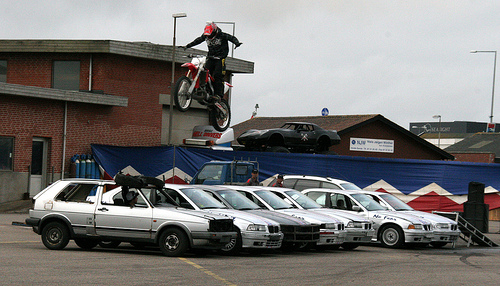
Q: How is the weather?
A: It is cloudy.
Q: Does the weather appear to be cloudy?
A: Yes, it is cloudy.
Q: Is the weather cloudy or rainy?
A: It is cloudy.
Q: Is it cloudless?
A: No, it is cloudy.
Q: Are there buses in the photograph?
A: No, there are no buses.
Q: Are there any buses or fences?
A: No, there are no buses or fences.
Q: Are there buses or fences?
A: No, there are no fences or buses.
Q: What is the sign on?
A: The sign is on the building.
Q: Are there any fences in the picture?
A: No, there are no fences.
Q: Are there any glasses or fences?
A: No, there are no fences or glasses.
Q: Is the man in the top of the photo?
A: Yes, the man is in the top of the image.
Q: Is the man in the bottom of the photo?
A: No, the man is in the top of the image.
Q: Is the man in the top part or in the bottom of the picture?
A: The man is in the top of the image.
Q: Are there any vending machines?
A: No, there are no vending machines.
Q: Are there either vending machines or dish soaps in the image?
A: No, there are no vending machines or dish soaps.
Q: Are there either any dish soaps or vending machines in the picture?
A: No, there are no vending machines or dish soaps.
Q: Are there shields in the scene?
A: No, there are no shields.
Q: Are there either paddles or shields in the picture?
A: No, there are no shields or paddles.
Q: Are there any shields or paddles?
A: No, there are no shields or paddles.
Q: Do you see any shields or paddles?
A: No, there are no shields or paddles.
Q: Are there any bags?
A: No, there are no bags.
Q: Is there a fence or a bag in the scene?
A: No, there are no bags or fences.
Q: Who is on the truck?
A: The people are on the truck.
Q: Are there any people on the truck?
A: Yes, there are people on the truck.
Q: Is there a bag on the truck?
A: No, there are people on the truck.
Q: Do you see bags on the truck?
A: No, there are people on the truck.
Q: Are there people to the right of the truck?
A: Yes, there are people to the right of the truck.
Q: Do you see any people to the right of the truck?
A: Yes, there are people to the right of the truck.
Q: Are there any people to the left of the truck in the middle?
A: No, the people are to the right of the truck.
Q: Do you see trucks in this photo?
A: Yes, there is a truck.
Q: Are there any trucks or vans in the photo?
A: Yes, there is a truck.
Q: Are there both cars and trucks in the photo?
A: Yes, there are both a truck and a car.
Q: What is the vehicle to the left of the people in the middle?
A: The vehicle is a truck.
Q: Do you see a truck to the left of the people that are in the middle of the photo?
A: Yes, there is a truck to the left of the people.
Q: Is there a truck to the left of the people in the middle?
A: Yes, there is a truck to the left of the people.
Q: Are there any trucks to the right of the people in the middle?
A: No, the truck is to the left of the people.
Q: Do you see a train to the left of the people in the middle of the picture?
A: No, there is a truck to the left of the people.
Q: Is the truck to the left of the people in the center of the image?
A: Yes, the truck is to the left of the people.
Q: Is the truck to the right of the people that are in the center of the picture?
A: No, the truck is to the left of the people.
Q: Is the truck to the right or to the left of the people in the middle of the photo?
A: The truck is to the left of the people.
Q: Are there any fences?
A: No, there are no fences.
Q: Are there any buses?
A: No, there are no buses.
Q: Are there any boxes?
A: No, there are no boxes.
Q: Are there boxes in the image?
A: No, there are no boxes.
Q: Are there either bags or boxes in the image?
A: No, there are no boxes or bags.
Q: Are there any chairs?
A: No, there are no chairs.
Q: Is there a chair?
A: No, there are no chairs.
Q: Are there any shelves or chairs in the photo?
A: No, there are no chairs or shelves.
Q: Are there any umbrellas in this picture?
A: No, there are no umbrellas.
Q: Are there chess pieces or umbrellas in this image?
A: No, there are no umbrellas or chess pieces.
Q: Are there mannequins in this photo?
A: No, there are no mannequins.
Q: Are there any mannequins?
A: No, there are no mannequins.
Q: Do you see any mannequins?
A: No, there are no mannequins.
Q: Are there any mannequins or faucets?
A: No, there are no mannequins or faucets.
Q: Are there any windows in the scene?
A: Yes, there is a window.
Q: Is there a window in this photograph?
A: Yes, there is a window.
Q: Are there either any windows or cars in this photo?
A: Yes, there is a window.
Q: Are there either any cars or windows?
A: Yes, there is a window.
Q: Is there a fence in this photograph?
A: No, there are no fences.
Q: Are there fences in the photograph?
A: No, there are no fences.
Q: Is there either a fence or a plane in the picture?
A: No, there are no fences or airplanes.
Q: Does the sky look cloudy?
A: Yes, the sky is cloudy.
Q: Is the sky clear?
A: No, the sky is cloudy.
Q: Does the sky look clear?
A: No, the sky is cloudy.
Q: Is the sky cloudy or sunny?
A: The sky is cloudy.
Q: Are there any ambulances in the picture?
A: No, there are no ambulances.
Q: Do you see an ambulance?
A: No, there are no ambulances.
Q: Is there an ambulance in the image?
A: No, there are no ambulances.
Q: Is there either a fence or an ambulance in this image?
A: No, there are no ambulances or fences.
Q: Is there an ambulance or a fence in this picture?
A: No, there are no ambulances or fences.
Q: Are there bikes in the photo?
A: Yes, there is a bike.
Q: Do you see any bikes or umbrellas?
A: Yes, there is a bike.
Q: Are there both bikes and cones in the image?
A: No, there is a bike but no cones.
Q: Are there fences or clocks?
A: No, there are no fences or clocks.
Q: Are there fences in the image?
A: No, there are no fences.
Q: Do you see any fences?
A: No, there are no fences.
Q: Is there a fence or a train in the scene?
A: No, there are no fences or trains.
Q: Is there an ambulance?
A: No, there are no ambulances.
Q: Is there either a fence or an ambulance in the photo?
A: No, there are no ambulances or fences.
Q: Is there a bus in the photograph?
A: No, there are no buses.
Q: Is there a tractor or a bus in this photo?
A: No, there are no buses or tractors.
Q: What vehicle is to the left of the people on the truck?
A: The vehicle is a car.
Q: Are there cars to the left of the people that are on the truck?
A: Yes, there is a car to the left of the people.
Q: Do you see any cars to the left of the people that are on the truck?
A: Yes, there is a car to the left of the people.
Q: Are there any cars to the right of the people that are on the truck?
A: No, the car is to the left of the people.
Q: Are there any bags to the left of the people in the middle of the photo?
A: No, there is a car to the left of the people.